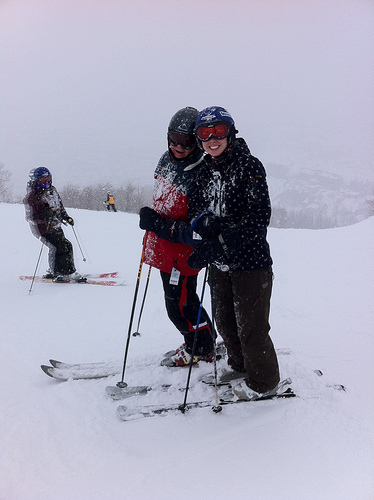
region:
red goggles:
[196, 124, 232, 138]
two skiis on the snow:
[100, 366, 362, 423]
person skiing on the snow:
[16, 162, 130, 309]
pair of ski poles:
[179, 260, 222, 416]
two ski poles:
[117, 246, 151, 390]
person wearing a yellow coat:
[102, 191, 118, 212]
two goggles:
[167, 117, 233, 145]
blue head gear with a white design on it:
[193, 106, 239, 125]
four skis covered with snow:
[43, 353, 367, 423]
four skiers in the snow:
[16, 103, 348, 433]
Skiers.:
[19, 79, 327, 403]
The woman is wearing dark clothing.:
[173, 101, 303, 402]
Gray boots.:
[194, 350, 296, 414]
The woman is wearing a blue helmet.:
[179, 105, 247, 164]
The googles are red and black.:
[191, 116, 234, 145]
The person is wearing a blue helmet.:
[25, 157, 57, 193]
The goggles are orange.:
[30, 172, 58, 184]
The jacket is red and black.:
[131, 156, 208, 270]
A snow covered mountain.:
[265, 155, 368, 227]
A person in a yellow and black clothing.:
[96, 179, 125, 218]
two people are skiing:
[89, 96, 372, 415]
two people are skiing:
[130, 112, 283, 374]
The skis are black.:
[131, 384, 301, 418]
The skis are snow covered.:
[57, 362, 126, 381]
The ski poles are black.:
[119, 322, 134, 354]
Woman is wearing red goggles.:
[190, 127, 239, 142]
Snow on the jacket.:
[201, 178, 233, 197]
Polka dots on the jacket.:
[212, 244, 281, 271]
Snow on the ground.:
[300, 152, 340, 177]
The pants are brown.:
[220, 293, 263, 316]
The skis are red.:
[63, 278, 112, 291]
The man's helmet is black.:
[170, 108, 201, 127]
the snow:
[42, 408, 124, 494]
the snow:
[63, 420, 172, 489]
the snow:
[117, 442, 173, 492]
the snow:
[18, 363, 156, 497]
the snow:
[60, 436, 135, 491]